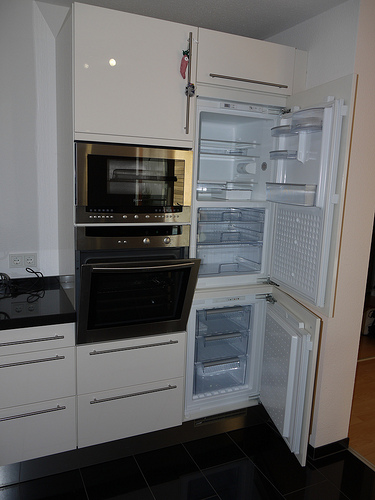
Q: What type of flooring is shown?
A: Tile.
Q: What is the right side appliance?
A: Refrigerator.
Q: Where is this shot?
A: Kitchen.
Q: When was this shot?
A: Daytime.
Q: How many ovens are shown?
A: 2.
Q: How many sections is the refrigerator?
A: 3.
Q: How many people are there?
A: 0.